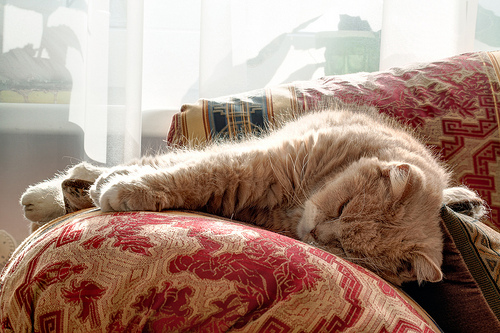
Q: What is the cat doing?
A: Sleeping.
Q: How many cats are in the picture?
A: 1.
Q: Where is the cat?
A: On the furniture.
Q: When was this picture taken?
A: Daytime.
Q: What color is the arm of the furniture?
A: Tan, cream, and red.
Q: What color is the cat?
A: Blonde.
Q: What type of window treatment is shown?
A: Sheers.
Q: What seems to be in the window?
A: Plants.